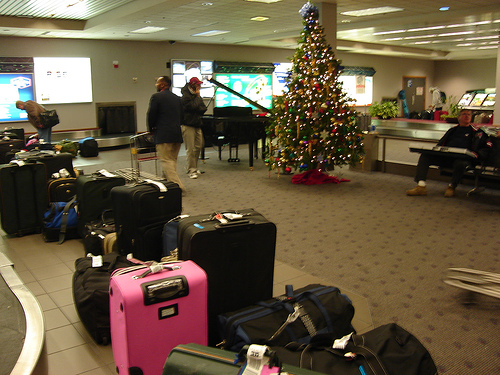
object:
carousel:
[0, 246, 52, 371]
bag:
[38, 107, 60, 124]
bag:
[73, 248, 120, 345]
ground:
[6, 166, 498, 368]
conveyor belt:
[79, 124, 150, 153]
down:
[405, 108, 473, 193]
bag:
[3, 160, 50, 236]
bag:
[108, 176, 185, 258]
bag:
[219, 278, 354, 350]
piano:
[197, 106, 274, 166]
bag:
[276, 320, 437, 374]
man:
[410, 108, 484, 200]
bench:
[459, 128, 496, 195]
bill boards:
[2, 59, 377, 114]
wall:
[2, 36, 434, 163]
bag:
[177, 205, 277, 356]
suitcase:
[110, 260, 211, 364]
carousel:
[0, 236, 45, 372]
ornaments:
[292, 56, 349, 138]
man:
[17, 100, 54, 140]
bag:
[105, 258, 210, 374]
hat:
[83, 137, 93, 149]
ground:
[8, 246, 161, 372]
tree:
[260, 0, 372, 181]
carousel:
[3, 251, 60, 372]